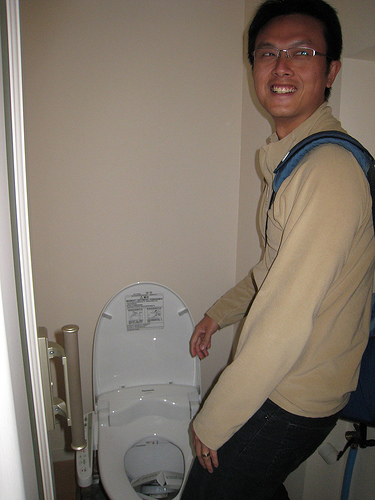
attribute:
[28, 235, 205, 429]
toilet bowl — white 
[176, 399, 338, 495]
jeans — dark, pair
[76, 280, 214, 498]
toilet — white 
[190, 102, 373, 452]
shirt — beige 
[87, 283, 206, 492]
toilet — white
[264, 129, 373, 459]
backpack — blue 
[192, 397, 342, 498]
jeans — blue, dark